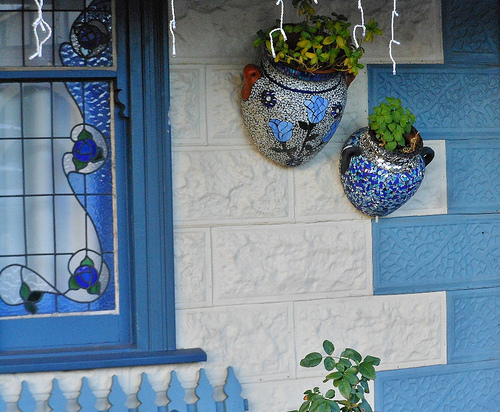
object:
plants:
[361, 93, 424, 161]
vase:
[234, 44, 356, 171]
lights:
[157, 0, 190, 60]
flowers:
[60, 122, 109, 177]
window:
[0, 0, 132, 359]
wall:
[175, 0, 235, 343]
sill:
[116, 0, 158, 351]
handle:
[234, 62, 263, 100]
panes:
[0, 59, 147, 124]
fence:
[0, 364, 248, 412]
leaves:
[305, 24, 345, 44]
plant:
[244, 0, 370, 82]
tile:
[437, 0, 496, 69]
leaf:
[69, 159, 104, 173]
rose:
[61, 244, 108, 301]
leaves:
[25, 281, 44, 315]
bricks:
[205, 218, 376, 311]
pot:
[333, 129, 436, 222]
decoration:
[0, 0, 124, 318]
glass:
[0, 82, 116, 319]